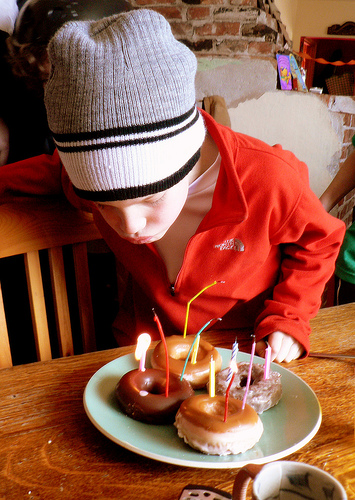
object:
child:
[31, 13, 335, 349]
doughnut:
[121, 369, 190, 413]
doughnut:
[159, 333, 214, 374]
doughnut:
[216, 357, 285, 411]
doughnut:
[186, 388, 269, 457]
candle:
[218, 370, 235, 420]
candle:
[180, 287, 198, 342]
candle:
[161, 345, 173, 396]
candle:
[260, 343, 273, 377]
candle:
[227, 336, 243, 370]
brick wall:
[127, 2, 291, 82]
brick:
[189, 12, 243, 40]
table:
[1, 300, 352, 497]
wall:
[195, 0, 354, 119]